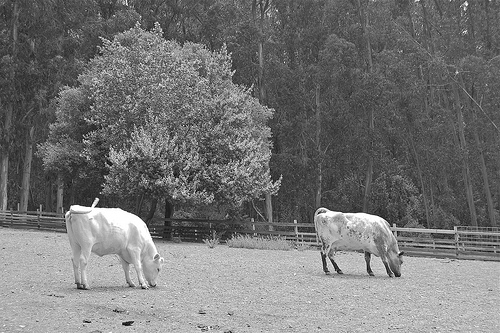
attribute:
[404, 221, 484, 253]
fence — wood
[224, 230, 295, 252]
plants — short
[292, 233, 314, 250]
plants — short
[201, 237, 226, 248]
plants — short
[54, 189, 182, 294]
cow — white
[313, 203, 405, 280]
pig — spotted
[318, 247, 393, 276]
legs — dark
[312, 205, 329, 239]
tail — curved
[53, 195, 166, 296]
pig — white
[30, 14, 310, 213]
tree — leafy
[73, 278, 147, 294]
shadow — faint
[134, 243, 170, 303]
head — bent down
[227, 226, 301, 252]
grass — short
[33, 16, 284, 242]
tree — leafy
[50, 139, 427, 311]
cows — eating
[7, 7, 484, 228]
trees — tall